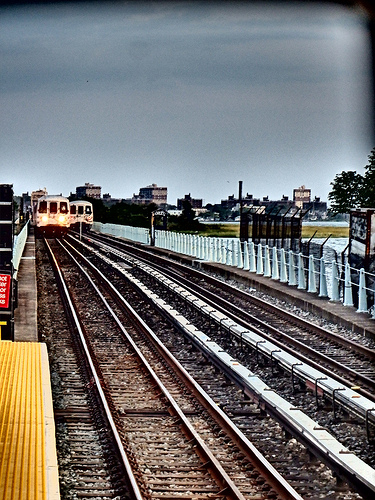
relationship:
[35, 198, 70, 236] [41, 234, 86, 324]
train coming down tracks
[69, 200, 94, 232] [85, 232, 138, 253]
train coming down tracks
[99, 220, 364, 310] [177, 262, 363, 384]
fence near tracks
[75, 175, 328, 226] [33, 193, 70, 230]
buildings behind train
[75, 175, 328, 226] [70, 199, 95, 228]
buildings behind train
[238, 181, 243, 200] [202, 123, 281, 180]
chimney jutting into sky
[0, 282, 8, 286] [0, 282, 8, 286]
lettering has lettering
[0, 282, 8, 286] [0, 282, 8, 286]
lettering on lettering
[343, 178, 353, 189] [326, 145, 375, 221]
leaves on tree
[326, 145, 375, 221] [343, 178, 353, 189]
tree has leaves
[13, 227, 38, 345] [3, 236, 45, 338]
platform for workers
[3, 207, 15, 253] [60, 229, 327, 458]
bed for tracks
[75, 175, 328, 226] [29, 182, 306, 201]
buildings in background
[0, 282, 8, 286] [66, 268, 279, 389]
lettering with bed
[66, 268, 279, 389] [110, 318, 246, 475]
bed on tracks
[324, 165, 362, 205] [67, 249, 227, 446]
tree on tracks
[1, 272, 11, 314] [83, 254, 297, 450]
bench on tracks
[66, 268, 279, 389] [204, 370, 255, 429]
bed with rocks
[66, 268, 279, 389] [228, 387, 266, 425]
bed with rocks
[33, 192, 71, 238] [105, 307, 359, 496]
train on tracks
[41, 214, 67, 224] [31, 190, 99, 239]
headlights of train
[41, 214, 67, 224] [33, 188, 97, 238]
headlights of train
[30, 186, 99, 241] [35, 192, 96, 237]
window of train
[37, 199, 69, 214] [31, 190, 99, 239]
train windows of train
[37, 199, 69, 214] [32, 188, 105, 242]
train windows of train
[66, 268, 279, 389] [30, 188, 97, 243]
bed for trains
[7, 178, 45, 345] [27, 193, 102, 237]
platform for train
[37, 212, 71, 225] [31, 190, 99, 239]
headlights approaching train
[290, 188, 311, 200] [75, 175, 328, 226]
billboard sign above buildings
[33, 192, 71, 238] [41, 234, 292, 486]
train on tracks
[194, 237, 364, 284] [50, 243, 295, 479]
fence beside tracks